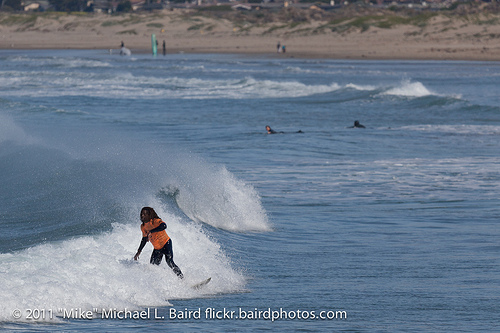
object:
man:
[132, 206, 186, 280]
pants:
[148, 238, 185, 279]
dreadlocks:
[139, 205, 161, 226]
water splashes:
[0, 111, 49, 214]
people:
[264, 125, 305, 135]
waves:
[171, 58, 313, 104]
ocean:
[0, 48, 499, 333]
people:
[275, 38, 282, 54]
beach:
[0, 0, 500, 61]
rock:
[117, 39, 133, 58]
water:
[0, 47, 499, 333]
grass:
[0, 1, 500, 41]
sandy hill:
[0, 0, 499, 62]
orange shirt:
[139, 218, 171, 250]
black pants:
[149, 238, 184, 280]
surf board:
[189, 276, 213, 291]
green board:
[150, 33, 158, 56]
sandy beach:
[0, 0, 500, 63]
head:
[353, 120, 359, 127]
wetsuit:
[348, 124, 366, 128]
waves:
[0, 216, 243, 324]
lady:
[133, 206, 185, 279]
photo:
[0, 0, 499, 333]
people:
[281, 45, 287, 53]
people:
[346, 120, 367, 130]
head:
[265, 125, 272, 131]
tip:
[187, 276, 212, 290]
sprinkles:
[133, 137, 205, 186]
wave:
[173, 174, 271, 234]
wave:
[293, 80, 434, 99]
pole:
[151, 33, 160, 57]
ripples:
[313, 159, 456, 208]